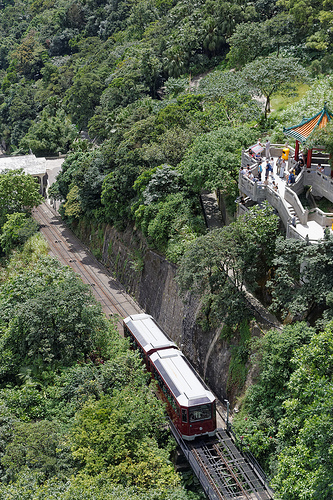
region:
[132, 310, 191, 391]
this is a train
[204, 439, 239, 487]
this is a railway line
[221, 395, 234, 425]
this is a pole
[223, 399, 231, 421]
the pole is white in color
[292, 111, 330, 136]
this is a building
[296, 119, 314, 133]
this is the roof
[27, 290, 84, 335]
this is a tree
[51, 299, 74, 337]
the leaves are green in color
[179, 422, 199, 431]
the train is red in color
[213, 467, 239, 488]
this is a metal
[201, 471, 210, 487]
part of a metal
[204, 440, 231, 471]
part of a metal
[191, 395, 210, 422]
part of a window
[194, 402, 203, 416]
part of a window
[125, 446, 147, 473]
par tof a tree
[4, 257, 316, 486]
photo taken from above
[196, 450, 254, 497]
train tracks for train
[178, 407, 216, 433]
red is on the front of train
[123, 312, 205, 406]
top of train is silver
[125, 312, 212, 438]
two train cars on the tracks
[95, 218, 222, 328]
side of mountain is rock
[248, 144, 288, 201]
people looking down at train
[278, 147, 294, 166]
person in yellow jacket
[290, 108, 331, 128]
orange and blue covering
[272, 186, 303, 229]
steps leading up to platform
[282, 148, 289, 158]
yellow trash can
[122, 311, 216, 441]
two car train on the tracks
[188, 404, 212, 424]
train has a windshield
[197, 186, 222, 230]
walk way under the trees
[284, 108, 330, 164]
Asian style patio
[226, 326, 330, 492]
bushes on the hillside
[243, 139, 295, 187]
people standing on the platform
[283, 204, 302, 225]
concrete steps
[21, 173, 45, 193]
train bridge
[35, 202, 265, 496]
a set of train tracks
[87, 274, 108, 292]
this is a railway line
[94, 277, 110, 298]
the railway is metallic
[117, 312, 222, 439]
this is a train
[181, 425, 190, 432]
the train is red in color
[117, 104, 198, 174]
these are some trees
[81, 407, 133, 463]
the leaves are big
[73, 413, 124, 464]
the leaves are green in color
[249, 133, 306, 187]
these are some people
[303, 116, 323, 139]
this is a roof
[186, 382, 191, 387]
the roof is white in color